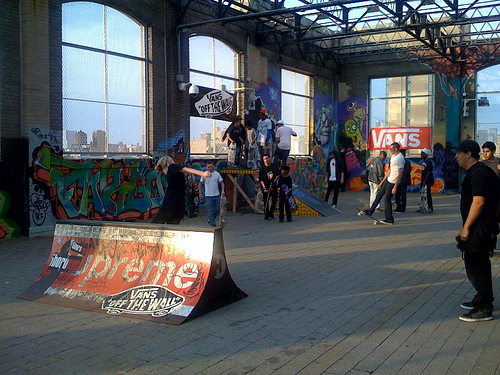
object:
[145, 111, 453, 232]
friends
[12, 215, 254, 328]
ramp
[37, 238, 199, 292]
supreme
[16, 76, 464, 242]
graffiti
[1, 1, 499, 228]
wall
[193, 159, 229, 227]
boy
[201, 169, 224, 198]
shirt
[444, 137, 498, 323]
man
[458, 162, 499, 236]
shirt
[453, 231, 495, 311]
pants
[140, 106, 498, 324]
people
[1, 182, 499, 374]
skatepark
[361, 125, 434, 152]
sign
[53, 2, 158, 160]
windows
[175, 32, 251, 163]
windows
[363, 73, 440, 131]
windows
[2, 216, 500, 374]
floor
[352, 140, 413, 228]
man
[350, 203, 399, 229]
board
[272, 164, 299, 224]
kid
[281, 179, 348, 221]
board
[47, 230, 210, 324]
graffiti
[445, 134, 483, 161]
hat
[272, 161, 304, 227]
boy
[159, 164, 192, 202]
shirt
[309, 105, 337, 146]
face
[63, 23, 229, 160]
city